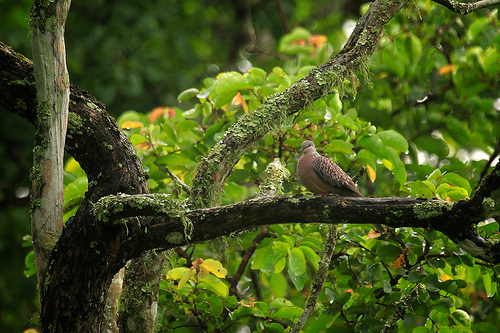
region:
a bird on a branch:
[278, 138, 358, 208]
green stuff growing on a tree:
[67, 189, 187, 228]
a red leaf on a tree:
[148, 105, 179, 117]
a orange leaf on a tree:
[436, 62, 473, 79]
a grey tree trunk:
[52, 48, 66, 155]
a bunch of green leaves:
[246, 245, 314, 269]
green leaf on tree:
[378, 148, 410, 186]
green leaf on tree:
[430, 302, 450, 319]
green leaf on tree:
[286, 245, 306, 277]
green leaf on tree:
[298, 244, 323, 274]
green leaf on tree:
[271, 301, 303, 321]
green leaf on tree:
[198, 255, 225, 278]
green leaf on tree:
[174, 266, 194, 291]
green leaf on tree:
[200, 270, 232, 301]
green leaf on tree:
[356, 133, 386, 158]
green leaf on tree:
[376, 128, 408, 160]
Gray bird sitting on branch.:
[298, 140, 358, 198]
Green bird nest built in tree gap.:
[91, 193, 198, 217]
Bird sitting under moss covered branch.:
[192, 52, 370, 197]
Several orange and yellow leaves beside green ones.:
[120, 102, 208, 149]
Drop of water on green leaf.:
[317, 94, 347, 133]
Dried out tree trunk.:
[22, 19, 71, 246]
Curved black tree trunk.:
[70, 95, 146, 194]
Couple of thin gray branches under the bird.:
[220, 223, 344, 328]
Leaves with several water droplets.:
[397, 234, 457, 287]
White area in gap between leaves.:
[405, 131, 498, 171]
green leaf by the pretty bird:
[285, 243, 306, 279]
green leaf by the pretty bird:
[203, 255, 226, 280]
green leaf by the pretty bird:
[432, 181, 467, 201]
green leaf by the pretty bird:
[376, 140, 407, 185]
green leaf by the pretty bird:
[318, 135, 351, 154]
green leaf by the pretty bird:
[378, 125, 409, 154]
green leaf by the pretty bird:
[151, 151, 198, 173]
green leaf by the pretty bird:
[297, 242, 317, 269]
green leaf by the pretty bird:
[252, 240, 288, 269]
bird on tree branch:
[275, 108, 334, 202]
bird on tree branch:
[268, 123, 379, 232]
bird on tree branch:
[264, 117, 371, 210]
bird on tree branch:
[280, 134, 374, 253]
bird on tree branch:
[277, 111, 377, 240]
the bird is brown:
[283, 125, 351, 229]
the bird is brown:
[275, 134, 367, 224]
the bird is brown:
[283, 119, 340, 181]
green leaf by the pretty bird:
[397, 174, 438, 201]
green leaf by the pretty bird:
[432, 183, 473, 206]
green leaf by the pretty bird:
[300, 245, 325, 272]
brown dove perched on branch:
[294, 139, 366, 196]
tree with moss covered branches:
[1, 0, 498, 331]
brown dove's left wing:
[312, 154, 362, 195]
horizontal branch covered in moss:
[190, 1, 408, 208]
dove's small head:
[297, 140, 314, 153]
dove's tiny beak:
[295, 145, 305, 153]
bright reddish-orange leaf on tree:
[147, 105, 174, 122]